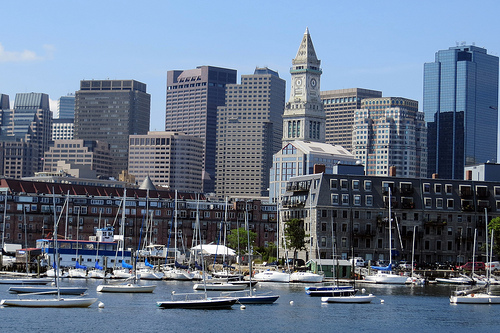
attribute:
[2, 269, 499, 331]
ocean — open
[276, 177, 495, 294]
building — low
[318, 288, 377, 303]
sail boat — white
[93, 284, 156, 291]
sail boat — white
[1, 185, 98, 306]
sail boat — white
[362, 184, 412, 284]
sail boat — white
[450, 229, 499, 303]
sail boat — white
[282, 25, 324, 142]
tower — pointed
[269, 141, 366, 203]
building — small, brown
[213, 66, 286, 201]
building — tan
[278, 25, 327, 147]
building — pointed, tall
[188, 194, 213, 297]
pole — tall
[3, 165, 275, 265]
building — small, brown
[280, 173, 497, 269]
building — small, brown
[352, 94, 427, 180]
building — small, brown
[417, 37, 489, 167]
building — small, brown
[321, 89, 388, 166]
building — small, brown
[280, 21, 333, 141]
building — small, brown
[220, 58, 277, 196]
building — small, brown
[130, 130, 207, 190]
building — small, brown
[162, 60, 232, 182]
building — small, brown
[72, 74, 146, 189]
building — small, brown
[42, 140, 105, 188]
building — small, brown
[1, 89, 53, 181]
building — small, brown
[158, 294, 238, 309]
boat — brown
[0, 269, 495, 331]
water — flat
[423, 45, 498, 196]
building — reflective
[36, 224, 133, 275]
boat — blue, white, red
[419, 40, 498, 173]
building — reflective, silver, tall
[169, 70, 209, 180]
building — tall, brown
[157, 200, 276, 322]
object — white, floating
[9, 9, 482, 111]
sky — blue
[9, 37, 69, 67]
cloud — small